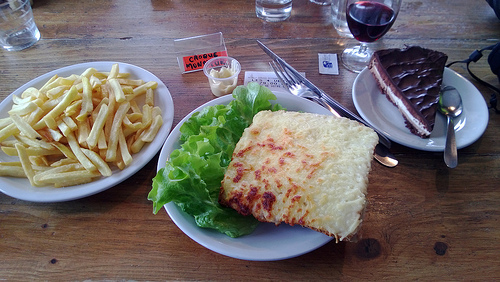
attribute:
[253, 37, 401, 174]
fork — silver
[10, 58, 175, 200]
plate — white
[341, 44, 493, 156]
plate — white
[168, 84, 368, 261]
plate — white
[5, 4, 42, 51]
bottle — clear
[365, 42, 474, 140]
cake — testy looking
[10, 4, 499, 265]
table — wooden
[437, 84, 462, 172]
spoon — small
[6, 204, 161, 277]
table — wooden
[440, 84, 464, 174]
spoon — metal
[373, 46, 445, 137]
pie — delicious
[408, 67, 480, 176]
spoon — shiny, silver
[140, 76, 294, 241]
lettuce — green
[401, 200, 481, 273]
table — wooden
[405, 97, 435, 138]
cake — portioned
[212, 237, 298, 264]
plate — white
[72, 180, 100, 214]
plate — white